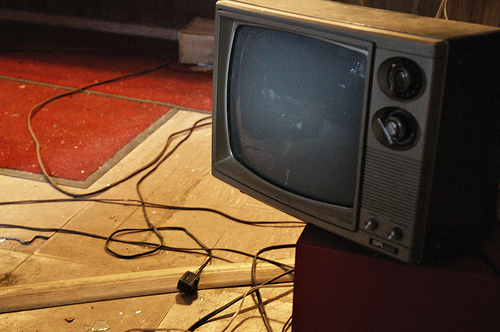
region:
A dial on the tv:
[376, 55, 428, 103]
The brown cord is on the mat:
[27, 61, 210, 191]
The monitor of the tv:
[227, 23, 369, 213]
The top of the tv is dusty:
[244, 1, 498, 36]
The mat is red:
[2, 75, 176, 182]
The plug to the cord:
[175, 270, 200, 296]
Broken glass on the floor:
[82, 317, 119, 330]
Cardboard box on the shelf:
[175, 14, 216, 71]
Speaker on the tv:
[362, 143, 422, 232]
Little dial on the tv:
[360, 217, 376, 235]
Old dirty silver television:
[205, 1, 498, 267]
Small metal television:
[206, 0, 496, 261]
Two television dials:
[367, 60, 422, 145]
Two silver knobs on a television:
[360, 215, 402, 241]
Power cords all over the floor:
[5, 55, 305, 326]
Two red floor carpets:
[0, 15, 215, 190]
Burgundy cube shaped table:
[286, 215, 496, 325]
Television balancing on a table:
[206, 0, 493, 326]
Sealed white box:
[177, 13, 216, 67]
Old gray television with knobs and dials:
[203, 0, 498, 269]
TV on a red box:
[210, 2, 460, 274]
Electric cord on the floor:
[98, 169, 287, 329]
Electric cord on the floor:
[24, 78, 219, 298]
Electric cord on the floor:
[181, 240, 297, 328]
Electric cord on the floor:
[76, 145, 226, 281]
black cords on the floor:
[7, 62, 344, 327]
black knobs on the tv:
[357, 60, 422, 249]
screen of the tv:
[223, 27, 354, 197]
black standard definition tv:
[200, 0, 494, 277]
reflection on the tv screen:
[238, 65, 362, 191]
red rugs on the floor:
[8, 52, 231, 181]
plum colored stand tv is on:
[290, 231, 494, 330]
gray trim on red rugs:
[2, 50, 193, 192]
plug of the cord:
[178, 270, 198, 293]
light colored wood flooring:
[1, 119, 284, 330]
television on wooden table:
[190, 0, 499, 270]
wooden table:
[284, 222, 494, 329]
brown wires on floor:
[0, 57, 302, 324]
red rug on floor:
[2, 25, 217, 197]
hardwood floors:
[1, 84, 303, 330]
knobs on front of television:
[370, 58, 427, 155]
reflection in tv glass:
[237, 35, 344, 179]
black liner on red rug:
[1, 101, 186, 198]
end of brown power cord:
[163, 257, 210, 299]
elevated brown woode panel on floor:
[4, 253, 296, 318]